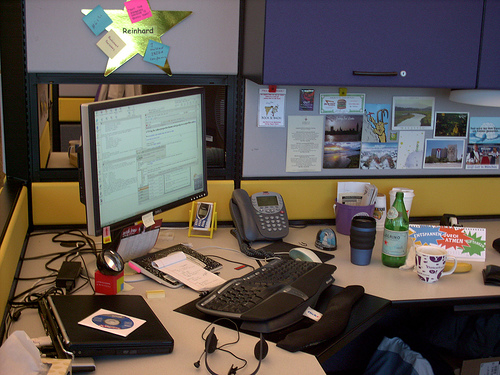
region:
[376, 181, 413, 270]
the bottle is green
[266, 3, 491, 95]
the cabinet is purple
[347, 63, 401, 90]
the handle is black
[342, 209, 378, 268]
the cup is on the desk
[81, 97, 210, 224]
the monitor is on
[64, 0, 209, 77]
the star is golden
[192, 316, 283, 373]
the headpiece is on the desk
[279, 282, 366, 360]
the armrest is black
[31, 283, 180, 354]
the laptop is closed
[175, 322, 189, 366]
the counter is tan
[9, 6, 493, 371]
picture taken inside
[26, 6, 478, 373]
picture taken indoors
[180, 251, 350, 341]
a black keyboard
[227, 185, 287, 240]
a gray telephone on desk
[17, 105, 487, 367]
equipment in a cubicle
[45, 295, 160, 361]
a laptop is closed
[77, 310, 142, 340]
a cd on the laptop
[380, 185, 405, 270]
a green bottle on desk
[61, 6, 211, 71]
a star on the door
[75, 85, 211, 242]
computer monitor sitting on desk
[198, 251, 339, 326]
black keyboard sitting on desk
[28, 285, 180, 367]
small notebook folded down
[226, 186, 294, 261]
gray corded phone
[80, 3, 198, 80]
green shiny star hanging up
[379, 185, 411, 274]
green San Pelligrino water bottle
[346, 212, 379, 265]
blue and black coffee mug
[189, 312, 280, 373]
set of black headphones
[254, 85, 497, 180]
pictures and memos pasted to wall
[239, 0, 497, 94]
blue cabinet with narrow black handle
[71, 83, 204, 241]
this is a computer monitor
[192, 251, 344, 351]
this is a computer keyboard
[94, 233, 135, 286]
this is a computer mouse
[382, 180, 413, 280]
this is a bottle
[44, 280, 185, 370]
this is a laptop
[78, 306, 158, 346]
this is a compact disk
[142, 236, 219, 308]
this is a note pad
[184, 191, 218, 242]
this is a picture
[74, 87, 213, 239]
A desktop computer screen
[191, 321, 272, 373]
A microphone and headset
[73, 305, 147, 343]
A DVD of computer software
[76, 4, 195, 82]
A gold star on the wall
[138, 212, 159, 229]
A post it note on the monitor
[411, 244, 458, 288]
A black and white coffee mug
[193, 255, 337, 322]
An ergonomic keyboard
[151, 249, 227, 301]
A writing pad on the desk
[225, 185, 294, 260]
A landline phone and cradle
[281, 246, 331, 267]
A white and green mouse